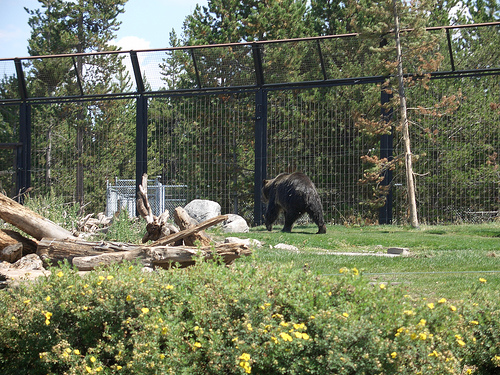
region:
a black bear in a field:
[257, 151, 374, 299]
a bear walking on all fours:
[211, 98, 424, 343]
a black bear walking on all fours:
[222, 119, 354, 285]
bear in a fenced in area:
[239, 101, 363, 230]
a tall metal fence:
[198, 68, 478, 315]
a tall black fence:
[58, 64, 490, 261]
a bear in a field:
[232, 145, 426, 301]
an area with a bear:
[165, 108, 493, 361]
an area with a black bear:
[232, 129, 420, 339]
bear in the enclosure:
[253, 167, 331, 238]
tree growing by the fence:
[381, 2, 426, 232]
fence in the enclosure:
[323, 90, 411, 218]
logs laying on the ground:
[11, 182, 227, 278]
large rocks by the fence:
[180, 191, 258, 227]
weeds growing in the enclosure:
[81, 287, 349, 359]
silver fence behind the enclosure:
[96, 165, 176, 221]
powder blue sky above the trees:
[131, 7, 164, 40]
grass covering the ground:
[407, 262, 481, 298]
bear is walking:
[248, 167, 334, 239]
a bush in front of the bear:
[8, 268, 477, 373]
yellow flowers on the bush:
[18, 291, 449, 371]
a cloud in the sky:
[107, 37, 164, 49]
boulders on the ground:
[179, 195, 237, 231]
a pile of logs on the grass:
[5, 201, 226, 277]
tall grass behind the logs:
[41, 190, 96, 232]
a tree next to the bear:
[366, 23, 443, 230]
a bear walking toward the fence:
[252, 175, 321, 222]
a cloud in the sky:
[116, 33, 162, 51]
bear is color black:
[248, 163, 335, 245]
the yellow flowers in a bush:
[228, 347, 260, 374]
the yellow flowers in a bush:
[274, 328, 295, 347]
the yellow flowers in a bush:
[423, 295, 438, 312]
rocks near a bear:
[178, 189, 293, 239]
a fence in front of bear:
[3, 13, 499, 244]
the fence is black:
[3, 19, 497, 227]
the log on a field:
[0, 187, 255, 288]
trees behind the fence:
[0, 0, 494, 220]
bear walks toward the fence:
[231, 157, 331, 241]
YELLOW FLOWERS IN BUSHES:
[122, 273, 369, 356]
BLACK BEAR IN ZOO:
[248, 154, 344, 241]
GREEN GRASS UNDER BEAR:
[301, 207, 476, 284]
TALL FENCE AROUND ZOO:
[12, 65, 479, 223]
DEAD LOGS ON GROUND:
[42, 185, 239, 275]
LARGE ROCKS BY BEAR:
[171, 182, 263, 246]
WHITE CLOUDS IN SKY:
[120, 24, 164, 61]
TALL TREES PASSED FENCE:
[67, 0, 498, 215]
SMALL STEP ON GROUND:
[390, 219, 415, 270]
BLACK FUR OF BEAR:
[267, 182, 314, 222]